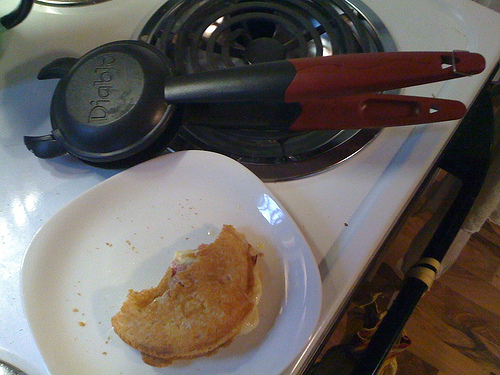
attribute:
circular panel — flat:
[20, 36, 160, 168]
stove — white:
[3, 0, 498, 373]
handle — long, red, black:
[174, 46, 486, 132]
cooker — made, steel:
[15, 7, 391, 174]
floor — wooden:
[312, 190, 490, 373]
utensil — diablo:
[13, 24, 490, 155]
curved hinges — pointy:
[21, 55, 78, 159]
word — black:
[82, 50, 126, 126]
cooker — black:
[20, 35, 489, 168]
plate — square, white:
[21, 148, 326, 373]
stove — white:
[118, 13, 404, 183]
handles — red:
[282, 48, 485, 133]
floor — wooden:
[343, 166, 487, 373]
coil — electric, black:
[139, 0, 381, 181]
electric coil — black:
[131, 0, 401, 189]